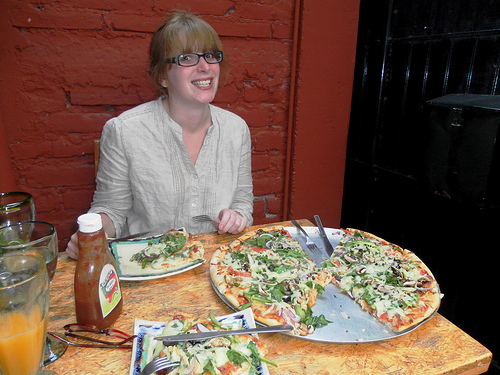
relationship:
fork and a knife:
[287, 214, 322, 256] [313, 213, 333, 258]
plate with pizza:
[131, 309, 263, 374] [147, 323, 261, 374]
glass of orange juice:
[2, 249, 48, 373] [0, 308, 47, 373]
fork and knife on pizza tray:
[290, 213, 332, 260] [209, 222, 443, 348]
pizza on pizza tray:
[211, 223, 442, 338] [209, 222, 443, 348]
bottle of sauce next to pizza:
[75, 213, 124, 333] [129, 227, 205, 269]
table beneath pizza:
[2, 219, 494, 374] [211, 223, 442, 338]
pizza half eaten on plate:
[129, 227, 205, 269] [110, 230, 206, 284]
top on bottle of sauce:
[78, 210, 103, 231] [75, 213, 124, 333]